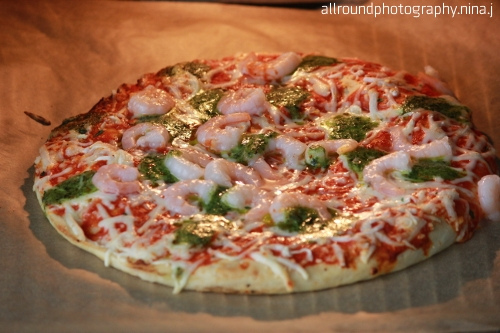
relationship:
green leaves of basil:
[333, 134, 374, 183] [340, 129, 389, 181]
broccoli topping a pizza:
[333, 107, 376, 146] [29, 52, 477, 295]